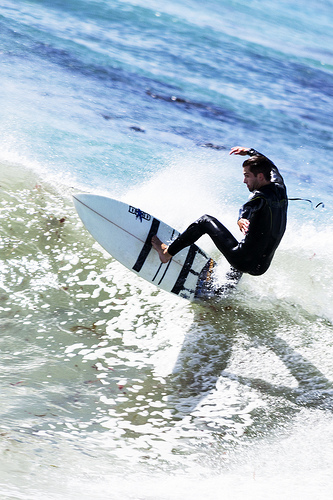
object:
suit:
[207, 173, 301, 270]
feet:
[155, 231, 248, 278]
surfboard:
[81, 200, 222, 293]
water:
[0, 14, 333, 500]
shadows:
[221, 312, 330, 396]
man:
[177, 72, 332, 275]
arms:
[207, 119, 315, 217]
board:
[68, 183, 156, 247]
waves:
[26, 159, 136, 300]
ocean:
[81, 20, 327, 140]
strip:
[93, 209, 181, 264]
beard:
[227, 180, 284, 203]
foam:
[109, 155, 221, 210]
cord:
[173, 287, 242, 339]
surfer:
[81, 148, 320, 373]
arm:
[229, 140, 284, 165]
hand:
[220, 136, 256, 173]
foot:
[146, 249, 197, 292]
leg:
[159, 218, 235, 257]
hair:
[239, 151, 282, 172]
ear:
[246, 165, 269, 182]